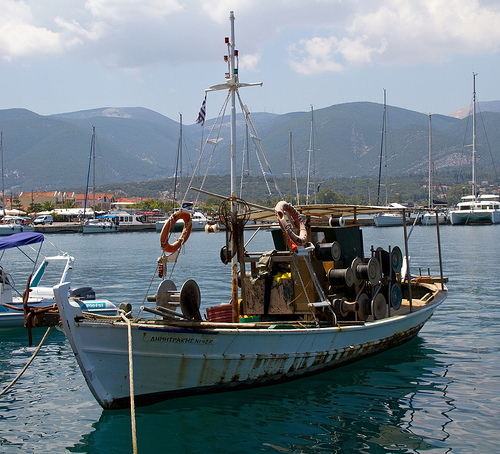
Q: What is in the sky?
A: Clouds.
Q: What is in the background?
A: Mountains.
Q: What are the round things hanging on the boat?
A: Life preservers.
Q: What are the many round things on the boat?
A: Spools.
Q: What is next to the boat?
A: Another boat.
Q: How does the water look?
A: Clear, blue.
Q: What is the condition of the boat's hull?
A: Rusted.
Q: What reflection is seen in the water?
A: The boat.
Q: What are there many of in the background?
A: Boats.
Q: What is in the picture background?
A: A range of mountains.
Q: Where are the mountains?
A: Far away in the distance.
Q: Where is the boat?
A: On the water.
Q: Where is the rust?
A: On the lower side of the boat.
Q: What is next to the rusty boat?
A: A small boat.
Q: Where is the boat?
A: In the harbor.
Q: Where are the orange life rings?
A: On the boat.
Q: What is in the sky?
A: Clouds.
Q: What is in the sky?
A: Clouds.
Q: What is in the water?
A: Boats.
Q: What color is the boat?
A: White.